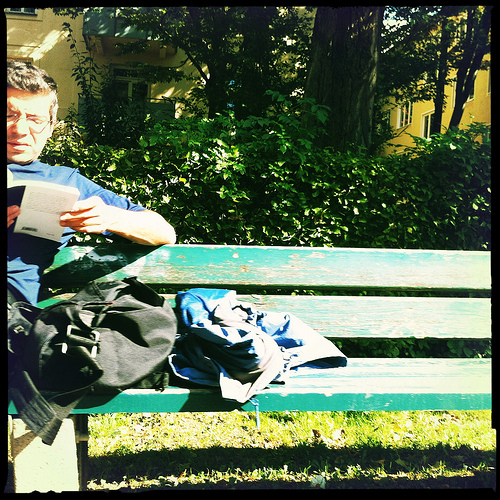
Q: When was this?
A: Daytime.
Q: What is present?
A: A bench.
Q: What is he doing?
A: Reading.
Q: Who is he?
A: A man.